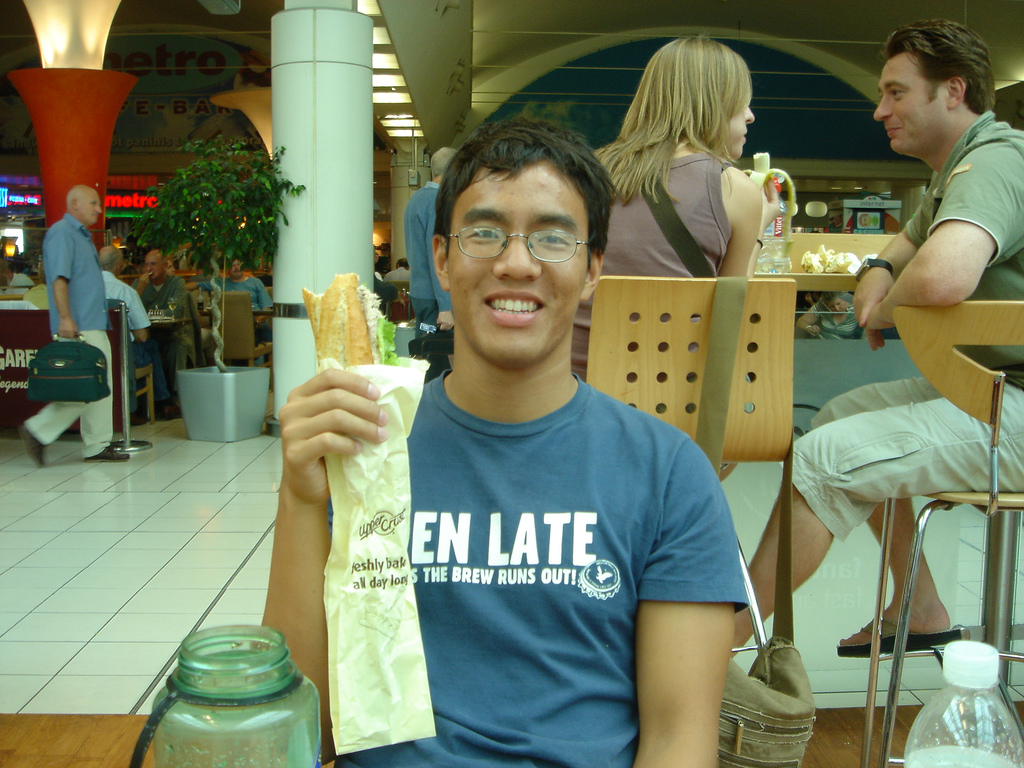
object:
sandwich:
[301, 273, 400, 371]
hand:
[280, 367, 390, 503]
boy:
[263, 117, 751, 768]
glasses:
[436, 224, 589, 262]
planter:
[129, 126, 305, 371]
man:
[20, 184, 130, 468]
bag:
[28, 333, 111, 402]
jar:
[154, 626, 326, 768]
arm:
[260, 475, 336, 768]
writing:
[410, 510, 623, 601]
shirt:
[336, 366, 752, 767]